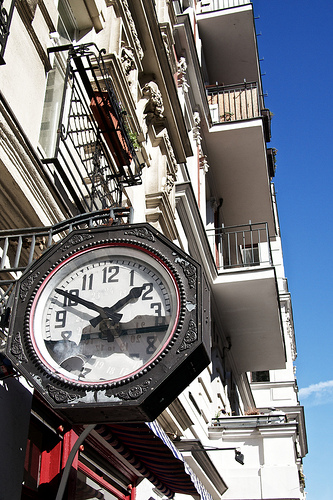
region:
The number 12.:
[101, 265, 120, 284]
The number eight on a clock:
[144, 334, 157, 354]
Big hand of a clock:
[53, 287, 122, 322]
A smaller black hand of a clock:
[88, 286, 143, 327]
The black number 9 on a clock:
[55, 310, 66, 328]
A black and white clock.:
[31, 242, 178, 386]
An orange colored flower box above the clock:
[93, 84, 135, 167]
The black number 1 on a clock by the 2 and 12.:
[128, 268, 133, 284]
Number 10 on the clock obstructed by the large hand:
[62, 287, 79, 305]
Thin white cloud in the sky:
[298, 381, 332, 403]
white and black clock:
[11, 225, 213, 423]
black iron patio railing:
[205, 224, 271, 276]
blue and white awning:
[99, 419, 213, 499]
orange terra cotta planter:
[91, 92, 136, 164]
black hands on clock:
[57, 286, 143, 325]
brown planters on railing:
[263, 108, 275, 176]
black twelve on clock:
[103, 266, 118, 283]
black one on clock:
[129, 269, 134, 285]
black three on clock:
[150, 303, 160, 318]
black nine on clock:
[55, 310, 65, 328]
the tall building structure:
[1, 0, 309, 499]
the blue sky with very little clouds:
[249, 0, 331, 499]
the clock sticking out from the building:
[4, 222, 210, 422]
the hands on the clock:
[51, 283, 144, 324]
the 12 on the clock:
[102, 266, 119, 282]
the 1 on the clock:
[129, 268, 134, 286]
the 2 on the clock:
[142, 282, 152, 299]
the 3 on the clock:
[149, 302, 160, 317]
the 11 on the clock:
[81, 274, 92, 289]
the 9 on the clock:
[53, 310, 65, 328]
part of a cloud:
[303, 361, 330, 419]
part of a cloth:
[246, 464, 269, 499]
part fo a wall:
[259, 446, 272, 464]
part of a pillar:
[272, 444, 283, 456]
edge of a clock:
[105, 385, 134, 411]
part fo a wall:
[248, 434, 263, 453]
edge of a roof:
[163, 444, 173, 472]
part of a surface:
[223, 129, 234, 141]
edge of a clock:
[106, 414, 137, 457]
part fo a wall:
[263, 436, 280, 458]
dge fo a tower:
[293, 458, 306, 477]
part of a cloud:
[306, 383, 321, 404]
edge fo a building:
[187, 459, 206, 490]